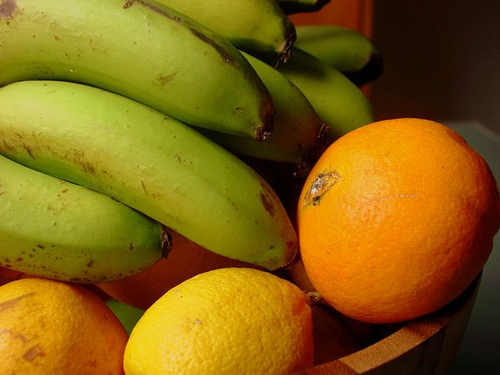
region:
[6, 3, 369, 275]
bunch of green bananas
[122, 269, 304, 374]
one lemon in bowl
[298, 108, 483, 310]
orange resting on bowl edge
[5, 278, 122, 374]
orange with banana resting on it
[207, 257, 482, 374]
edge of brown bowl fruit is in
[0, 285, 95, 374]
dark marks on orange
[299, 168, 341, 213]
white and black spot on orange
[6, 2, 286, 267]
discolorations on green bananas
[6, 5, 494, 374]
fruits in brown bowl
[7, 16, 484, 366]
bowl holding bananas, lemon, oranges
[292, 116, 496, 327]
Orange in wooden basket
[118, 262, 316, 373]
Yellow lemon in basket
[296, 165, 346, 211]
Bruise on orange in basket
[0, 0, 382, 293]
Green bananas in basket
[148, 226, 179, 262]
Stem on green banana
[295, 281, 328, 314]
Stem on yellow lemon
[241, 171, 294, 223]
Brown spot on green banana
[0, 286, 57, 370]
Brown spots on orange fruit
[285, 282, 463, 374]
Wooden basket fruits are in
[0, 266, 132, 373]
Yellow orange fruit in basket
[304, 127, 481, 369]
the orange is orange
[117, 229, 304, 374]
the lemon is round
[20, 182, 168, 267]
the banana is unppelled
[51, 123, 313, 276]
the banana is green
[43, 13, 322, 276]
the bananas are in a bunch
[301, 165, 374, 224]
a scar is on the orange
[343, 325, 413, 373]
the bowl is wooden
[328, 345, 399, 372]
the bowl is brown and red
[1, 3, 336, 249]
the banans are si x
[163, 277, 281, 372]
the lemon is uncut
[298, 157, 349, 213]
spiderweb, i think, smashed upon an orange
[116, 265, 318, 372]
a lemon, seemingly whole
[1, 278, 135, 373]
orange, again? not quite ripe, w/ scratches?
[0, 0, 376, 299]
a number of completely unripe bananas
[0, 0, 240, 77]
green, yet already beginning to bruise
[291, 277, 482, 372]
wood dish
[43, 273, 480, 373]
bottom of wooden dish covered in fruit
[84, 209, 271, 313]
i think it's a papaya, but it's mostly hidden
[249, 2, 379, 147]
something in the back, probably made out of wood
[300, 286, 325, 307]
some citrus stem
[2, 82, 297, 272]
a yellow green banana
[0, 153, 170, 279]
a yellow green banana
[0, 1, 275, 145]
a yellow green banana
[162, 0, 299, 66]
a yellow green banana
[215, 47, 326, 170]
a yellow green banana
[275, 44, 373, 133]
a yellow green banana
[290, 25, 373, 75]
a yellow green banana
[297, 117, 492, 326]
a round orange fruit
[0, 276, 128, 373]
a round orange fruit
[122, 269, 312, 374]
a ripe yellow lemon